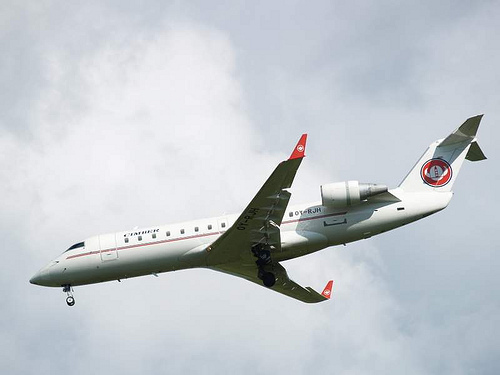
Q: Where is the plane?
A: In the sky.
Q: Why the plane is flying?
A: To travel.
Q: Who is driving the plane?
A: The pilot.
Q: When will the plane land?
A: Later.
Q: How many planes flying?
A: One.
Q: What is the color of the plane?
A: White.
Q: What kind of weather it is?
A: Calm.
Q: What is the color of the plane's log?
A: Red.